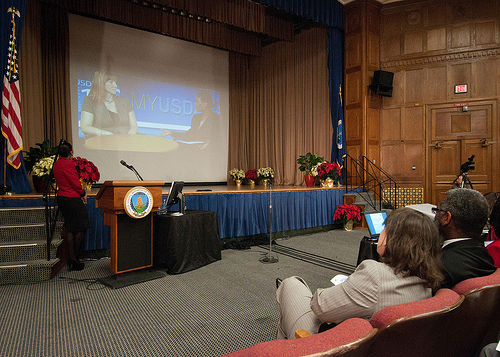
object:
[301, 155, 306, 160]
leaf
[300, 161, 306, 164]
leaf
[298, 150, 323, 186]
plant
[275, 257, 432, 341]
suit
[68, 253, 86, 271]
boots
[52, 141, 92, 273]
woman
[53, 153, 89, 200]
shirt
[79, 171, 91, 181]
flowers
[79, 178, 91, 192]
vase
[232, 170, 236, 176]
flowers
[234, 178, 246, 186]
pot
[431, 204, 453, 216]
glasses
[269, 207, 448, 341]
woman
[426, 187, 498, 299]
man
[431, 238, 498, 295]
suit jacket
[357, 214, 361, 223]
flowers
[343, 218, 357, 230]
vase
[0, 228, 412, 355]
floor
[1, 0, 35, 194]
flag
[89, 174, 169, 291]
podium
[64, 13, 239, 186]
screen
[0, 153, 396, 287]
stage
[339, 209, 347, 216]
flowers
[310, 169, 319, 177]
flowers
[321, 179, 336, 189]
pot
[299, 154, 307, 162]
flowers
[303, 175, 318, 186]
pot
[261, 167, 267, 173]
flowers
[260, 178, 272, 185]
pot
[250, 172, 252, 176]
flowers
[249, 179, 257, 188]
pot